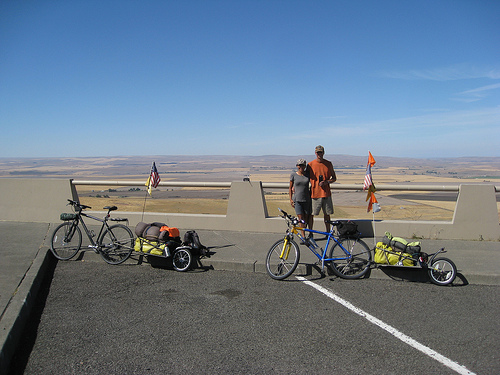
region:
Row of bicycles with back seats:
[49, 197, 469, 290]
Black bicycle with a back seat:
[49, 201, 135, 263]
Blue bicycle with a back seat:
[260, 206, 373, 283]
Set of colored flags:
[364, 148, 383, 245]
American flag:
[139, 161, 164, 227]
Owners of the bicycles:
[291, 145, 339, 241]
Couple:
[284, 144, 336, 244]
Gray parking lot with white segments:
[2, 244, 497, 374]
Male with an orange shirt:
[303, 144, 338, 244]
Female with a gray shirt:
[286, 159, 318, 244]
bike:
[53, 189, 209, 280]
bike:
[252, 168, 445, 297]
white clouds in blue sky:
[62, 16, 160, 81]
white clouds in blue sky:
[46, 74, 93, 113]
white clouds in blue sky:
[130, 99, 173, 131]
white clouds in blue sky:
[221, 30, 257, 72]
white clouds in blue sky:
[328, 33, 367, 58]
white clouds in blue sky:
[361, 71, 436, 102]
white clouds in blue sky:
[216, 58, 240, 76]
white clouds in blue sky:
[58, 59, 98, 83]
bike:
[272, 203, 360, 280]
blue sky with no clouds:
[33, 40, 65, 85]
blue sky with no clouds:
[235, 10, 263, 47]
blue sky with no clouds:
[392, 85, 425, 125]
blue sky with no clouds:
[135, 7, 175, 54]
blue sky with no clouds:
[190, 80, 241, 118]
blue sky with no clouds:
[65, 71, 110, 116]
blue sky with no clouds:
[110, 53, 162, 106]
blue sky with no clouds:
[38, 36, 91, 88]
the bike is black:
[48, 190, 148, 269]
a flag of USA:
[134, 154, 181, 196]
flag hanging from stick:
[144, 163, 163, 191]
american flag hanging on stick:
[362, 158, 378, 194]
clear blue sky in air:
[121, 42, 297, 82]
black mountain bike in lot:
[52, 198, 140, 271]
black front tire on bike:
[52, 222, 85, 260]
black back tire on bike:
[97, 222, 135, 262]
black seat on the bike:
[101, 203, 119, 214]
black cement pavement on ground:
[122, 322, 202, 373]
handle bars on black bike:
[70, 196, 91, 206]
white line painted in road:
[315, 281, 495, 371]